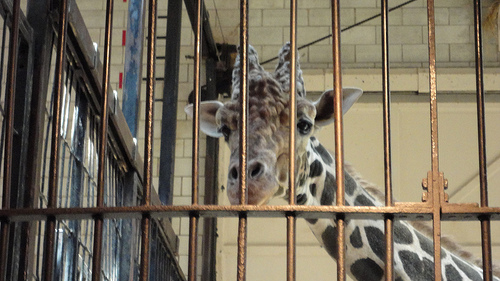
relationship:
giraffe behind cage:
[182, 39, 493, 280] [1, 2, 499, 276]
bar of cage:
[5, 201, 496, 216] [1, 2, 499, 276]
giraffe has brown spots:
[182, 39, 493, 280] [247, 77, 284, 120]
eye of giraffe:
[297, 113, 315, 133] [182, 39, 493, 280]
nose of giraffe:
[227, 157, 269, 181] [182, 39, 493, 280]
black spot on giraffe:
[363, 223, 397, 266] [182, 39, 493, 280]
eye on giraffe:
[297, 113, 315, 133] [182, 39, 493, 280]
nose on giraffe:
[227, 157, 269, 181] [182, 39, 493, 280]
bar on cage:
[5, 201, 496, 216] [1, 2, 499, 276]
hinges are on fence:
[69, 44, 104, 79] [40, 10, 184, 276]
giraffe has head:
[182, 39, 493, 280] [184, 40, 362, 216]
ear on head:
[311, 80, 366, 124] [184, 40, 362, 216]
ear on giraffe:
[311, 80, 366, 124] [182, 39, 493, 280]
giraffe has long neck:
[182, 39, 493, 280] [306, 141, 479, 278]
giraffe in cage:
[182, 39, 493, 280] [1, 2, 499, 276]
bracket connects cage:
[389, 151, 478, 214] [1, 2, 499, 276]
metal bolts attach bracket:
[420, 174, 452, 189] [389, 151, 478, 214]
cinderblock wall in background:
[96, 15, 480, 67] [63, 7, 500, 218]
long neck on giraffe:
[306, 141, 479, 278] [182, 39, 493, 280]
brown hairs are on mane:
[369, 183, 380, 196] [306, 141, 479, 278]